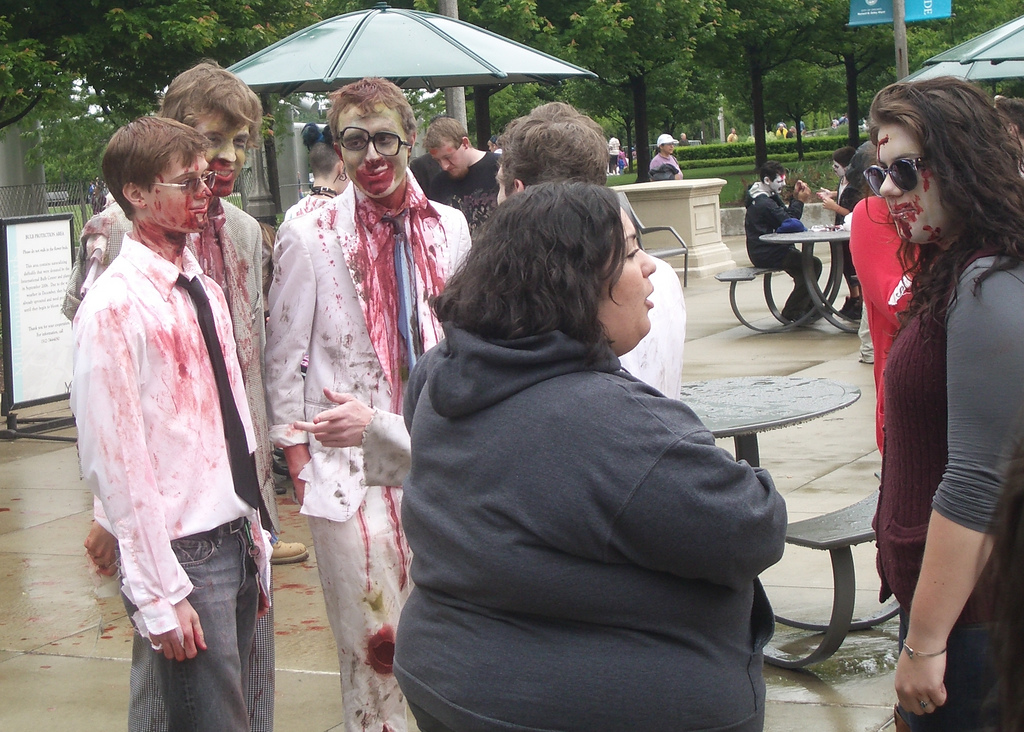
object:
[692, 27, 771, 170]
leaves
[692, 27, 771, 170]
tree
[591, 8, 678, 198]
tree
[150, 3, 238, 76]
leaves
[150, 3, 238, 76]
tree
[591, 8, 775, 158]
leaves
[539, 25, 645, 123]
leaves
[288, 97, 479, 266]
paint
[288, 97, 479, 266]
face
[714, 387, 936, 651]
table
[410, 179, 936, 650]
women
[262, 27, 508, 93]
umbrella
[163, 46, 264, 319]
boys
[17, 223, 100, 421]
sign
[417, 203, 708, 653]
lady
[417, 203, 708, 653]
hoodie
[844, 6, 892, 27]
signs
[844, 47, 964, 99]
pole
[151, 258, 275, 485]
tie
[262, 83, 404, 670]
boy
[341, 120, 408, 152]
glasses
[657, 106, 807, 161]
people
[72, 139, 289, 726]
boy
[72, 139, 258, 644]
shirt